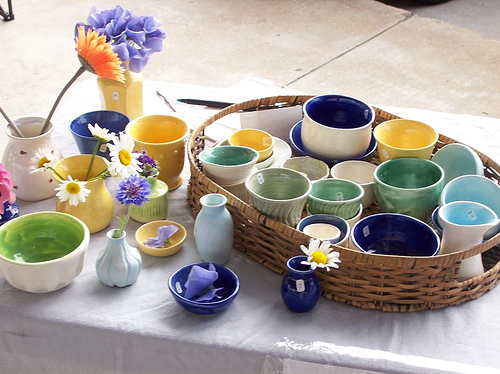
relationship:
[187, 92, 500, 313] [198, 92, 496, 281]
basket holding containers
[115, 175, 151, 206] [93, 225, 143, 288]
flower in vase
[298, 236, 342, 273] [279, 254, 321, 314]
daisy in container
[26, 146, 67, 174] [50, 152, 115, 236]
daisy in container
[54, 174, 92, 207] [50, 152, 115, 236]
daisy in container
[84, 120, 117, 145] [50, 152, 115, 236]
daisy in container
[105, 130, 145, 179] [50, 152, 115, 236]
daisy in container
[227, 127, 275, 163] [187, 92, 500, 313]
container in basket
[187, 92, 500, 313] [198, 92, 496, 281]
basket holds cups and vases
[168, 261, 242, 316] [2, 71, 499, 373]
bowl on table cloth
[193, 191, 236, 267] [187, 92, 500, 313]
vase outside basket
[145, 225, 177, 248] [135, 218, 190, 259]
petal in bowl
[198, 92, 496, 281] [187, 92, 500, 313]
containers are in basket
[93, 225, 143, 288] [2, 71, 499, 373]
vase on table cloth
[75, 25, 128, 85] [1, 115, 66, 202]
sunflower in vase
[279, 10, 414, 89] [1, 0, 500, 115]
crack in sidewalk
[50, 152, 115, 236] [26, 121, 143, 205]
container holds daisies